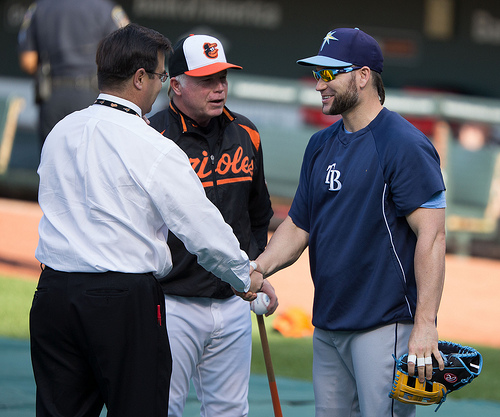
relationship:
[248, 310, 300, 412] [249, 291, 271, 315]
bat next to baseball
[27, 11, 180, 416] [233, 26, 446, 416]
man near player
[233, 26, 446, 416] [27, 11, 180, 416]
player near man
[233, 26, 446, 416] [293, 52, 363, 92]
player wearing sunglasses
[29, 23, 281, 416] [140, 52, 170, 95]
man wearing glasses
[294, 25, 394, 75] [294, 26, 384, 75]
hat on hat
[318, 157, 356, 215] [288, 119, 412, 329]
logo on shirt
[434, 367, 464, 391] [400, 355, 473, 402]
logo on glove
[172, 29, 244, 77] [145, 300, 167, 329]
cap in pen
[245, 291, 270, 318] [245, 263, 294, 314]
baseball in hand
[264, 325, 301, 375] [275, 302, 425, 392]
grass on field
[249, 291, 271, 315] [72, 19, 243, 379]
baseball held by man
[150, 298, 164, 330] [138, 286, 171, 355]
pen in pocket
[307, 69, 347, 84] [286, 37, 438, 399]
sunglasses worn by player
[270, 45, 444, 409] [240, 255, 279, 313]
player shaking hand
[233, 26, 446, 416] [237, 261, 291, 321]
player shaking hand